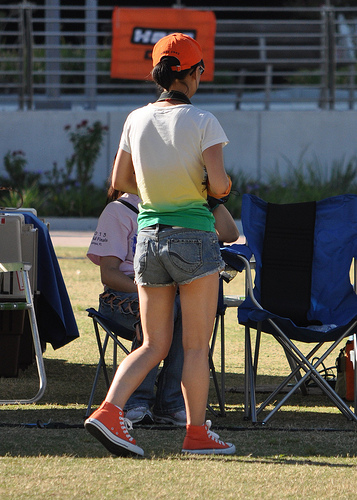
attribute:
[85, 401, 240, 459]
sneaker — orange   , white   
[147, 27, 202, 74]
cap — orange 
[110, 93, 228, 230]
shirt — white  , green tea 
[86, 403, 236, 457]
shoes — orange 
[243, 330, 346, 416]
base — silver 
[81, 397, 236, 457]
shoes — orange 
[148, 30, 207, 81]
hat — girls orange 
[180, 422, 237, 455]
sneaker — orange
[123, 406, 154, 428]
sneaker — black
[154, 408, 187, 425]
sneaker — black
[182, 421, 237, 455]
shoe — orange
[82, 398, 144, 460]
shoe — orange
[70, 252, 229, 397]
black lawn chair — black lawn, blue 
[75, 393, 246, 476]
orange sneaker — left orange 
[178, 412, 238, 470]
right orange sneaker — right orange 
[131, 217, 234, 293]
jean shorts — jean 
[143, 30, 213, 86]
baseball cap — orange baseball c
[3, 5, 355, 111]
metal fence — metal 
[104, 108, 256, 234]
green t shirt — green , tan yellow 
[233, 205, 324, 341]
black chair — black , blue 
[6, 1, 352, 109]
thin grey fence — thin grey 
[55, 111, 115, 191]
green rose bush — green rose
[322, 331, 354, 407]
dark brown cart — dark brown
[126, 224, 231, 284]
blue jeans — blue 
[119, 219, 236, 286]
blue jean shorts — blue jean 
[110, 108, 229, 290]
back of a girl — back 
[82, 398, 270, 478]
sneakers on a woman — white , Orange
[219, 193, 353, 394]
blue chair — blue 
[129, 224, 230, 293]
blue jean shorts — Blue jean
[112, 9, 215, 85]
sign past the people — orange 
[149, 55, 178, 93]
black pony tail — Black pony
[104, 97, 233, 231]
short sleeved shirt — short sleeved